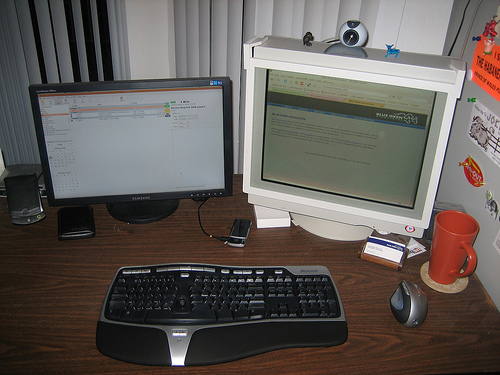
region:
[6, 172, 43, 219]
a speaker on the desk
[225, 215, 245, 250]
a cell phone on the desk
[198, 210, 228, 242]
a charging cord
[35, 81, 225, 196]
the screen of the computer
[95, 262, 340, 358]
a keyboard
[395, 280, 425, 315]
a computer mouse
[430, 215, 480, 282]
a red mug on the desk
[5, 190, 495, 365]
a wooden desk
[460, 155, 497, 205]
stickers on the wall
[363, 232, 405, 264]
a stack of business cards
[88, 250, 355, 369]
a keyboard is on the table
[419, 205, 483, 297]
a coffee mug is to the right of the keyboard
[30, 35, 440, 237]
two different monitors sit on the desk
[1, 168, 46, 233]
a desktop speaker sits to the left of the monitor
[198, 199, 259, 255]
a cell phone is on the desk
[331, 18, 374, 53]
a web cam is placed on top of the monitor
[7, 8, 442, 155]
blinds are in the background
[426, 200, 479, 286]
the coffee mug is orange in color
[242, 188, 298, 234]
a small pad of paper for notes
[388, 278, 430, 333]
a wireless mouse on the desk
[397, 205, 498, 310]
The cup is orange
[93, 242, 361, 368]
The keyboard is black and silver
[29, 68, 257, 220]
The screen is on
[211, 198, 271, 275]
The phone is plugged in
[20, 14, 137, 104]
It is dark out the window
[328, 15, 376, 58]
The webcam is on the screen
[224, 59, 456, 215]
The screen is on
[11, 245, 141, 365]
The desk is wooden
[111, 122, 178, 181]
The screen is white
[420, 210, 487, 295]
The cup has a handle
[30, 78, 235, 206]
a black monitor on a desk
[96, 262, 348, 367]
a black and silver keyboard on a desk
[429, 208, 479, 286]
a red mug on a coaster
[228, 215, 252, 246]
a cell phone on a desk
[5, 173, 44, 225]
a gray speaker on a desk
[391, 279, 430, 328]
a wireless silver and black mouse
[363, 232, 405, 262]
white and blue business cards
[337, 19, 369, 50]
a circular webcam on top of a monitor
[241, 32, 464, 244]
a white computer monitor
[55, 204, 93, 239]
a black leathery wallet on a desk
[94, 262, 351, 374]
a silver and black keyboard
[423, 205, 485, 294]
a tall red coffee cup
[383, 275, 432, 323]
a silver and black wireless mouse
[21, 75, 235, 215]
a monitor to a computer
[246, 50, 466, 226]
a monitor to a computer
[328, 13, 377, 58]
a small round web cam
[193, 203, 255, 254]
a cellphone being charged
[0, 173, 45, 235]
a silver computer speaker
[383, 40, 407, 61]
a small plastic horse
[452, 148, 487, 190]
a red and white sticker